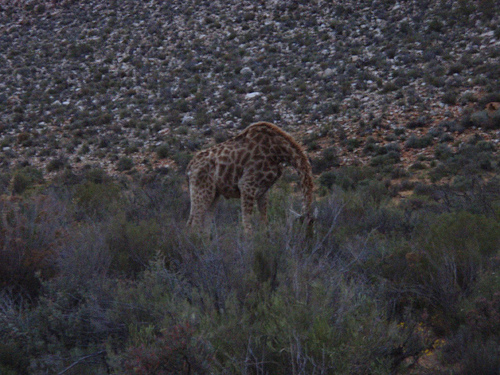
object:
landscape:
[0, 1, 500, 198]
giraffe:
[182, 119, 319, 242]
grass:
[1, 154, 499, 375]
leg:
[239, 193, 256, 235]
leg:
[256, 193, 271, 232]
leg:
[185, 181, 217, 234]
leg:
[207, 191, 221, 242]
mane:
[245, 120, 314, 208]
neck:
[279, 130, 316, 211]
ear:
[284, 208, 301, 223]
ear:
[305, 203, 317, 220]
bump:
[192, 158, 212, 187]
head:
[288, 208, 320, 257]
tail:
[184, 169, 192, 231]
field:
[1, 3, 500, 375]